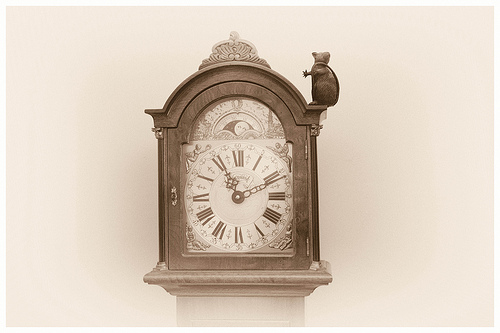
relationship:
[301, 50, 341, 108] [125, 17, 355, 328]
mouse on top of clock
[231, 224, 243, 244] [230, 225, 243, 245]
roman numeral for number six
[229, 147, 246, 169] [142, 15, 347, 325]
xii on clock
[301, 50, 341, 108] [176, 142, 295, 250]
mouse on side of a clock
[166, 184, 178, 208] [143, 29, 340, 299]
knob on left of a clock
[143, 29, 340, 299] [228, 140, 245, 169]
clock with roman numeral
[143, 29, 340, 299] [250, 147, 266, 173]
clock with roman numeral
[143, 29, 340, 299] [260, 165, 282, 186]
clock with roman numeral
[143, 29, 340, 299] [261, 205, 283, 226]
clock with roman numeral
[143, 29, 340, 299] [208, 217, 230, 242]
clock with roman numeral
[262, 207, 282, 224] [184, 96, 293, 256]
roman numeral on analogue clock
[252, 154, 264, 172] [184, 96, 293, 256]
roman numeral on analogue clock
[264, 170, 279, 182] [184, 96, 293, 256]
roman numeral on analogue clock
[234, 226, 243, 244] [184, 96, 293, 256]
roman numeral on analogue clock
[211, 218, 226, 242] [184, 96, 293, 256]
roman numerals on analogue clock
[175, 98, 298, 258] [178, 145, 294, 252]
glass door on clock face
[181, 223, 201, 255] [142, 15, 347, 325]
drawing on clock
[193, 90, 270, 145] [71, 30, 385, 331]
drawing on clock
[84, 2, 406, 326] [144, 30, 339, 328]
clock on tower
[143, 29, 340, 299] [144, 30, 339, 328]
clock on tower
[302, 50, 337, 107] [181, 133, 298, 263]
animal on clock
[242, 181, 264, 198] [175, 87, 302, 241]
arm on clock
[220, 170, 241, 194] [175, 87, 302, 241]
arm on clock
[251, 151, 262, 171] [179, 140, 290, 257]
roman numeral on clock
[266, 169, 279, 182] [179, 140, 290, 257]
roman numeral on clock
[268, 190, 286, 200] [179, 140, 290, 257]
roman numeral on clock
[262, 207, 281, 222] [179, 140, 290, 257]
roman numeral on clock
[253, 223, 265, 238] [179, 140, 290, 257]
roman numeral on clock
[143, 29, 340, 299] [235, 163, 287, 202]
clock has hand